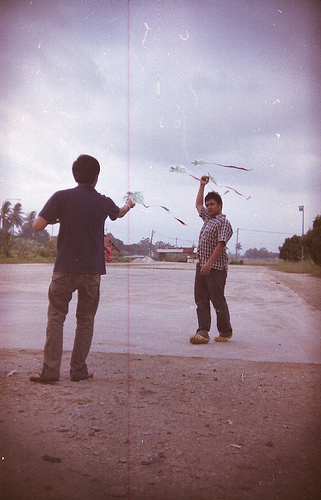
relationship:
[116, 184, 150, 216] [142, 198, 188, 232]
kite with tail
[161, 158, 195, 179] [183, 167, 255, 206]
kite with tail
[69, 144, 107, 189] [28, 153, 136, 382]
head of people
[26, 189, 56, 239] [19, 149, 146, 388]
arm of person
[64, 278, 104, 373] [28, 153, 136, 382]
leg of people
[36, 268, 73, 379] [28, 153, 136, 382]
leg of people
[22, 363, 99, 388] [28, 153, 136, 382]
feet of people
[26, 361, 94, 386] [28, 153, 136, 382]
feet of people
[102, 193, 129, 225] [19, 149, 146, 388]
arm of person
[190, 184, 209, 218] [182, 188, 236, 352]
arm of person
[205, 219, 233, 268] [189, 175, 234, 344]
arm of man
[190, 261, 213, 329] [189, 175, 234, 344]
leg of man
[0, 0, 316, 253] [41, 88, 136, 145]
sky has clouds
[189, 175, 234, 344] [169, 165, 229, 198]
man with kite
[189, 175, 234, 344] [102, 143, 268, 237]
man with kites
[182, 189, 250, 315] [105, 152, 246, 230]
man with kites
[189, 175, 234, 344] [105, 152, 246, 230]
man with kites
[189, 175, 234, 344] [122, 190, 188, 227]
man with kite